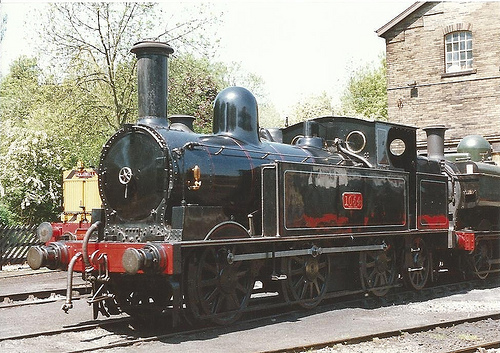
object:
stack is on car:
[130, 40, 175, 127]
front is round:
[96, 120, 172, 222]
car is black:
[448, 158, 498, 285]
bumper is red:
[27, 240, 175, 278]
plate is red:
[342, 192, 363, 210]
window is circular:
[345, 130, 366, 153]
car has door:
[384, 127, 419, 230]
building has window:
[439, 30, 480, 75]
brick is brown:
[456, 21, 464, 30]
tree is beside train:
[20, 1, 229, 176]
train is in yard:
[26, 36, 498, 329]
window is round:
[388, 136, 408, 157]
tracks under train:
[116, 272, 500, 315]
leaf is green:
[214, 36, 224, 45]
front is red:
[37, 218, 96, 246]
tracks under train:
[0, 303, 132, 353]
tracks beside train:
[253, 314, 500, 352]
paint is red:
[423, 213, 449, 228]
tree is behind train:
[346, 50, 389, 123]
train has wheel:
[184, 229, 261, 328]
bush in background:
[1, 189, 34, 230]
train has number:
[343, 194, 349, 207]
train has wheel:
[281, 240, 330, 309]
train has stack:
[419, 125, 451, 158]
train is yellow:
[59, 162, 101, 222]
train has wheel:
[358, 230, 396, 297]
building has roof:
[375, 2, 439, 40]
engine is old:
[24, 36, 454, 332]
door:
[388, 124, 418, 231]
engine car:
[22, 39, 456, 329]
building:
[375, 0, 500, 131]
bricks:
[428, 102, 443, 110]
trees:
[0, 57, 69, 220]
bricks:
[398, 109, 414, 119]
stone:
[447, 111, 500, 124]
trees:
[121, 51, 231, 143]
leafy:
[20, 141, 66, 215]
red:
[49, 241, 176, 273]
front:
[24, 257, 194, 341]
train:
[29, 35, 500, 335]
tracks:
[0, 267, 500, 353]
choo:
[5, 302, 500, 353]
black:
[302, 190, 327, 210]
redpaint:
[110, 256, 120, 270]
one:
[29, 0, 226, 131]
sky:
[0, 0, 375, 107]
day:
[6, 0, 393, 115]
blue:
[262, 0, 358, 55]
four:
[184, 234, 437, 327]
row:
[147, 233, 457, 327]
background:
[16, 71, 497, 123]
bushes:
[29, 101, 120, 170]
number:
[342, 191, 363, 209]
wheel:
[108, 267, 175, 320]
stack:
[164, 114, 195, 134]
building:
[60, 159, 108, 220]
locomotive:
[79, 87, 466, 324]